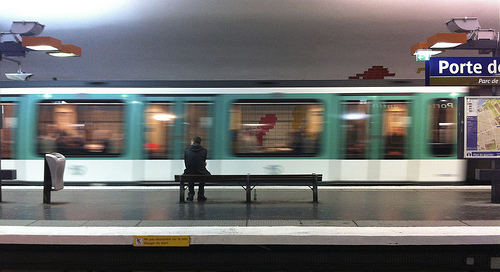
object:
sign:
[425, 56, 500, 85]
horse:
[172, 174, 323, 203]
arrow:
[416, 53, 430, 61]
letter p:
[439, 60, 449, 73]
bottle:
[253, 189, 257, 201]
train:
[0, 86, 475, 189]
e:
[473, 63, 482, 74]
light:
[427, 32, 467, 49]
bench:
[173, 172, 323, 203]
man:
[184, 136, 210, 201]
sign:
[415, 53, 430, 61]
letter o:
[449, 63, 460, 74]